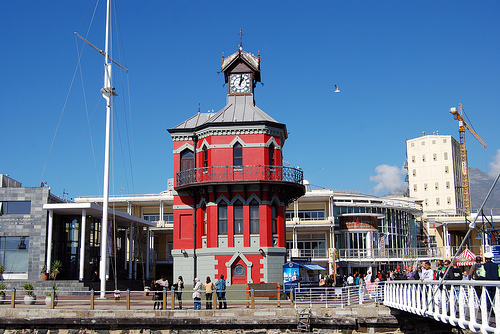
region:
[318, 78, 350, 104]
bird flying in clear sky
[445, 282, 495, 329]
white wooden guard rail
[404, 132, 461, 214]
large building with windows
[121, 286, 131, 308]
brown wooden fence post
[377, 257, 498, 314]
people standing beside guard rail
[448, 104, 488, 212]
large orange metal crane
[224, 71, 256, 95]
large clock on building roof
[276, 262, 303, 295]
blue sign beside building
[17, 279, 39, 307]
plant in grey pot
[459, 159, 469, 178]
sign on side of metal crane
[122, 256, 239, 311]
The people are standing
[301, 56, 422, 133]
The sky is blue and clear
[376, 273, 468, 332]
The bridge is metal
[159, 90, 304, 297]
The building is red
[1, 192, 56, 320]
The building has many windows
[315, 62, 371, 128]
The bird is flying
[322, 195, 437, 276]
The building is round shaped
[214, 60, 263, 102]
The clock is on the top of the building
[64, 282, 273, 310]
The people are behind the fence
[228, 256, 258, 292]
The door is shut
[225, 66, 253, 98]
clock with roman numerals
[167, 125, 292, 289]
red and grey building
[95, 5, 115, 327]
tall white flag pole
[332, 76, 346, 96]
sea gull flying in air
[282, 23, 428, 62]
clear cloudless blue sky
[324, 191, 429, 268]
round building with many windows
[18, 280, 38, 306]
plant in gray pot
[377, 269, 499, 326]
bridge with white railing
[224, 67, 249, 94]
clock reading 1:02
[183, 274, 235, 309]
tourists standing near building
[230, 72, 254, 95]
clock in clock tower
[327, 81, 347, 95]
black and white bird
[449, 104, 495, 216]
crane in the background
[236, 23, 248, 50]
cross on top of clocktower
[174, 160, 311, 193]
balcony around clock tower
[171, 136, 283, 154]
four arches over windows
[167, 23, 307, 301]
red and grey clock tower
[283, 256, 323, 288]
small blue building with awning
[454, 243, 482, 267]
red and white tent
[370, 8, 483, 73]
cloudless blue sky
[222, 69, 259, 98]
A clock on the building,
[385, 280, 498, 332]
Railing for the bridge.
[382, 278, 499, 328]
A white span bridge.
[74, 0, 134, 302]
Pole for a sail.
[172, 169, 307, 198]
A black balcony.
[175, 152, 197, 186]
A door to the balcony.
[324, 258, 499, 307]
A crowd of people.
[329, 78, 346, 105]
A sea gull in the air.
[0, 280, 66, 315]
A line of plants.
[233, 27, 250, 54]
The steeple of the tower.